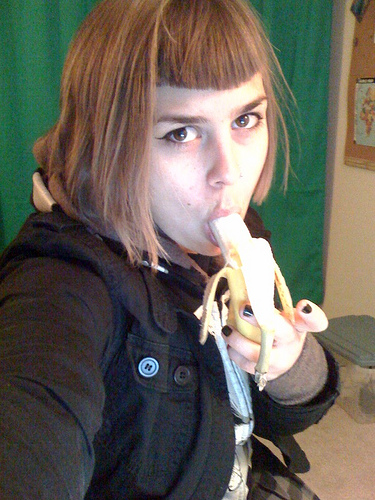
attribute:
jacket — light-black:
[0, 205, 340, 498]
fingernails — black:
[220, 300, 312, 337]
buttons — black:
[140, 356, 195, 390]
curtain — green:
[0, 0, 334, 309]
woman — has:
[0, 2, 347, 498]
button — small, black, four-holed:
[137, 357, 158, 382]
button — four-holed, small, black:
[175, 366, 192, 386]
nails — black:
[301, 301, 313, 318]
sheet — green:
[1, 0, 333, 308]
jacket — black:
[33, 222, 300, 415]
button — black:
[168, 362, 194, 388]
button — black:
[136, 354, 162, 381]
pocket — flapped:
[101, 333, 200, 477]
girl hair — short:
[130, 3, 267, 101]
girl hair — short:
[68, 0, 150, 255]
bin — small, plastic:
[311, 314, 373, 424]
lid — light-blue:
[308, 315, 369, 363]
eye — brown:
[164, 125, 199, 142]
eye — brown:
[232, 112, 259, 129]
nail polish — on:
[299, 303, 314, 314]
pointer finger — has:
[290, 298, 328, 332]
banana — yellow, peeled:
[204, 211, 277, 365]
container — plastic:
[344, 369, 373, 410]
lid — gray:
[331, 310, 373, 367]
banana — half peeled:
[209, 211, 251, 259]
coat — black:
[7, 166, 339, 498]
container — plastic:
[314, 309, 371, 426]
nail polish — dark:
[301, 303, 312, 313]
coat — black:
[13, 248, 211, 495]